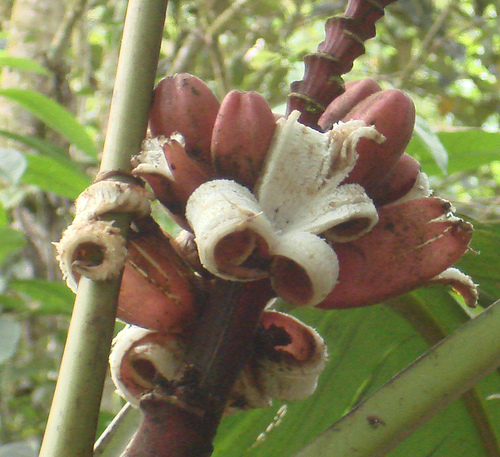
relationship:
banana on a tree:
[145, 69, 215, 167] [2, 0, 489, 454]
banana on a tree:
[208, 86, 273, 179] [2, 0, 489, 454]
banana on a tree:
[330, 87, 417, 179] [2, 0, 489, 454]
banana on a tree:
[60, 175, 204, 335] [2, 0, 489, 454]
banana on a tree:
[197, 107, 466, 407] [2, 0, 489, 454]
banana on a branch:
[332, 94, 414, 184] [41, 1, 169, 455]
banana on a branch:
[197, 107, 466, 407] [41, 1, 169, 455]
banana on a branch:
[145, 69, 215, 167] [41, 1, 169, 455]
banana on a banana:
[197, 107, 466, 407] [332, 94, 414, 184]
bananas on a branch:
[90, 60, 482, 328] [41, 1, 169, 455]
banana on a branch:
[330, 87, 417, 179] [41, 1, 169, 455]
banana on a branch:
[60, 175, 204, 335] [41, 1, 169, 455]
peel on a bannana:
[64, 126, 476, 391] [83, 66, 474, 379]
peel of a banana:
[184, 108, 379, 307] [210, 84, 276, 184]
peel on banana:
[224, 304, 330, 411] [47, 70, 480, 412]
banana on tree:
[60, 175, 204, 335] [83, 6, 450, 454]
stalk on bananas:
[118, 0, 392, 455] [90, 60, 482, 328]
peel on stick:
[67, 199, 149, 267] [76, 15, 114, 433]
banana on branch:
[197, 107, 466, 407] [122, 0, 387, 453]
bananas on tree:
[90, 60, 482, 328] [2, 0, 489, 454]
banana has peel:
[197, 107, 466, 407] [178, 110, 386, 316]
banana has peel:
[197, 107, 466, 407] [157, 138, 193, 170]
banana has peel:
[195, 307, 338, 412] [222, 360, 272, 412]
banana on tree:
[197, 107, 466, 407] [46, 4, 402, 416]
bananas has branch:
[108, 98, 318, 315] [388, 14, 444, 83]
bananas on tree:
[93, 81, 473, 391] [2, 0, 489, 454]